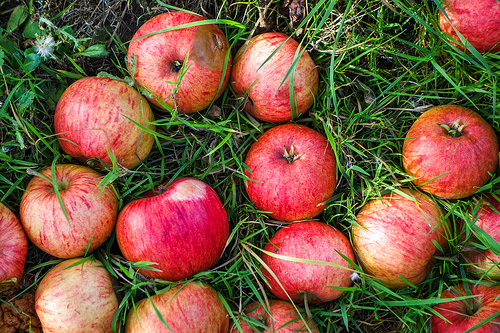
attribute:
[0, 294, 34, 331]
dirt — patch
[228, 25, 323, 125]
apple — red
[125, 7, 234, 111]
apple — red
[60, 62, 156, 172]
apple — red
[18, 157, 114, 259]
apple — red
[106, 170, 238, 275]
apple — red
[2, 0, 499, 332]
grass — green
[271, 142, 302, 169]
apple bottom — red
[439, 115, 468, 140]
apple bottom — red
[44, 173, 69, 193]
apple bottom — red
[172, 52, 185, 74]
apple bottom — red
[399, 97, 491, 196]
apple — red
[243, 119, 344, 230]
apple — red, juicy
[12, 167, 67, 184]
stem — green, brown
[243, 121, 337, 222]
apple — red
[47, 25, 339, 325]
fruit — red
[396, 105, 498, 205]
apple — red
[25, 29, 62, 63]
spore — white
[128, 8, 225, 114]
apple — red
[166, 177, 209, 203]
patch — pale, yellow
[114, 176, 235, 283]
apple — red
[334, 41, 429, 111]
patch — empty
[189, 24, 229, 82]
spot — rotten, brown